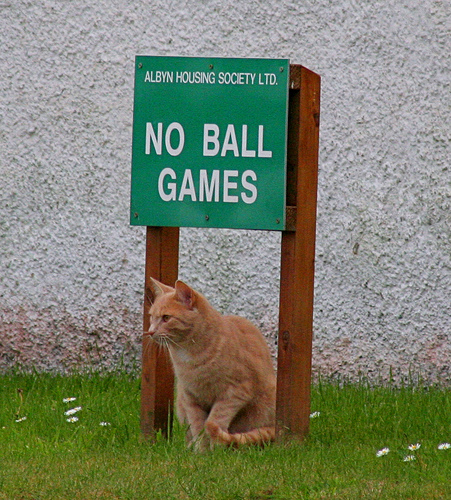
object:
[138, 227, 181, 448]
poles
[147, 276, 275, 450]
cat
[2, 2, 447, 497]
outdoors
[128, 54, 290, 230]
sign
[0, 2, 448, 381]
wall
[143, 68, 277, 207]
posts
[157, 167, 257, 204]
lettering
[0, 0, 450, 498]
daytime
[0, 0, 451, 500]
photo